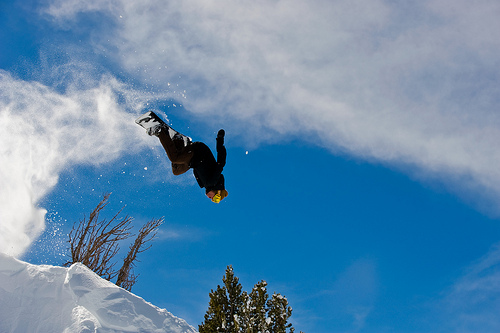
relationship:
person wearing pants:
[149, 124, 233, 201] [160, 130, 198, 185]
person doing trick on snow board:
[148, 124, 228, 204] [124, 103, 170, 136]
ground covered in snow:
[0, 255, 197, 331] [0, 250, 197, 331]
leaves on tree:
[226, 300, 266, 322] [197, 257, 289, 327]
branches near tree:
[61, 190, 165, 293] [194, 266, 296, 330]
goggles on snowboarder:
[209, 192, 226, 204] [147, 100, 232, 204]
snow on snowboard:
[145, 108, 161, 132] [133, 110, 189, 155]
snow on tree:
[259, 284, 266, 293] [189, 265, 300, 331]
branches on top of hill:
[56, 190, 148, 282] [2, 233, 194, 331]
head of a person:
[205, 187, 229, 204] [134, 107, 229, 202]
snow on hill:
[0, 250, 197, 331] [7, 253, 191, 331]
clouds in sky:
[33, 0, 497, 195] [0, 3, 498, 331]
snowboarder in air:
[132, 102, 232, 209] [288, 200, 440, 276]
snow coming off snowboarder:
[0, 59, 166, 261] [135, 110, 160, 131]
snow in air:
[6, 264, 120, 331] [180, 208, 447, 260]